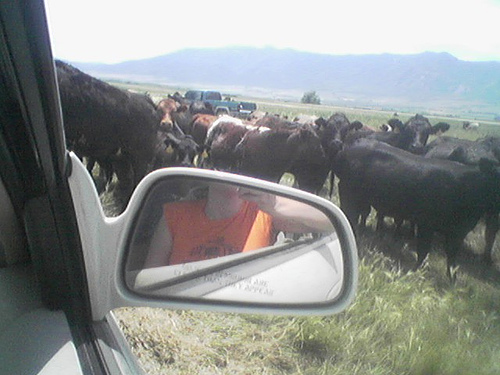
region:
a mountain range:
[61, 42, 499, 104]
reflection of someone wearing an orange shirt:
[121, 175, 347, 303]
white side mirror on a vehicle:
[66, 150, 360, 323]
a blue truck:
[168, 86, 258, 118]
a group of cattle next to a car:
[59, 61, 499, 286]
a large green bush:
[300, 91, 322, 105]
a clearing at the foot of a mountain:
[108, 75, 498, 143]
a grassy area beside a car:
[113, 238, 494, 369]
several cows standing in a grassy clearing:
[51, 55, 499, 286]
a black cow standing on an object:
[51, 60, 159, 200]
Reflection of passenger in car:
[152, 167, 328, 304]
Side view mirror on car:
[118, 158, 363, 321]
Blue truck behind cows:
[163, 80, 258, 122]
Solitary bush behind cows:
[290, 80, 332, 113]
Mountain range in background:
[141, 23, 478, 100]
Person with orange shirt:
[163, 172, 278, 283]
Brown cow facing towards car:
[143, 85, 190, 137]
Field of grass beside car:
[377, 249, 479, 371]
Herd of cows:
[62, 62, 494, 254]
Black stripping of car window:
[6, 48, 131, 373]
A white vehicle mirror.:
[64, 148, 359, 324]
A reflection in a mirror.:
[126, 177, 343, 307]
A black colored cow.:
[335, 138, 499, 285]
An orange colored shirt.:
[162, 200, 274, 266]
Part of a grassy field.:
[108, 205, 498, 373]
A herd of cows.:
[53, 53, 499, 284]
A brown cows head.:
[154, 95, 189, 132]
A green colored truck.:
[181, 87, 258, 119]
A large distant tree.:
[298, 90, 321, 105]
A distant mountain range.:
[65, 43, 499, 103]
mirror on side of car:
[105, 137, 405, 339]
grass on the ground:
[338, 285, 435, 367]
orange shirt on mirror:
[142, 195, 272, 273]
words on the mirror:
[170, 242, 293, 299]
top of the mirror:
[150, 154, 306, 210]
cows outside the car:
[149, 79, 460, 207]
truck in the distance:
[164, 80, 266, 132]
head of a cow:
[306, 100, 363, 157]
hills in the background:
[181, 22, 449, 84]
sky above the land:
[164, 2, 366, 53]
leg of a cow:
[417, 227, 480, 287]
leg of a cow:
[391, 210, 439, 271]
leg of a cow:
[377, 208, 424, 263]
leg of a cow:
[374, 210, 409, 248]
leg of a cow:
[358, 204, 385, 243]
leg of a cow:
[105, 163, 135, 190]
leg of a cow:
[90, 146, 104, 179]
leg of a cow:
[288, 163, 320, 195]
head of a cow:
[147, 78, 194, 137]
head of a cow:
[168, 137, 225, 160]